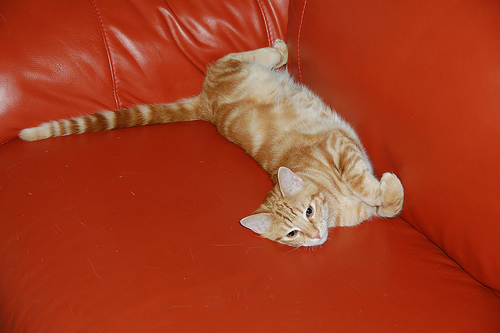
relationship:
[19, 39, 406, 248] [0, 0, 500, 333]
cat lying on a couch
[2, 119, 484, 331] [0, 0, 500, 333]
cushion of a couch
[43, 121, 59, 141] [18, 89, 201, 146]
stripe on tail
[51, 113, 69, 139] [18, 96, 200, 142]
stripe on tail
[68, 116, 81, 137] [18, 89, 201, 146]
stripe on tail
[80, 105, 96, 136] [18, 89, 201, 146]
stripe on tail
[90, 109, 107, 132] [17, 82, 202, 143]
stripe on tail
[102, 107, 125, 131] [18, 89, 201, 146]
stripe on tail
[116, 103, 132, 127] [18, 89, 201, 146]
stripe on tail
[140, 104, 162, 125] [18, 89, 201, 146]
stripe on tail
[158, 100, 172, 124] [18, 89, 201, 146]
stripe on tail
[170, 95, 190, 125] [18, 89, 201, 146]
stripe on tail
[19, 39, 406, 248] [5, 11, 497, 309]
cat laying on a couch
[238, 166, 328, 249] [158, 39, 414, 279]
head of a cat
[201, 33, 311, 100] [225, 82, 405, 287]
feet of a cat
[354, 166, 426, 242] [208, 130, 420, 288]
paws on cat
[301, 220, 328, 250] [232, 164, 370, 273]
nose on cat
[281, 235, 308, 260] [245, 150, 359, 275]
whiskers on cat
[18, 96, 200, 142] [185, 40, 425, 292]
tail of a cat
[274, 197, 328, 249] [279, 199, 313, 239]
cat with eyes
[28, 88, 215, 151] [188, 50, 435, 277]
tail of a cat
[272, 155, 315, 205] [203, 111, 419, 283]
ear of a cat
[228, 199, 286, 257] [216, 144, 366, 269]
ear of a cat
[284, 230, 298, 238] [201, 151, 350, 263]
eye of a cat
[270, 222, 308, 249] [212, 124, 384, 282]
eye of a cat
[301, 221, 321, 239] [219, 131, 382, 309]
nose of a cat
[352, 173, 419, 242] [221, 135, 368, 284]
legs of a cat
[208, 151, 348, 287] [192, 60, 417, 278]
head of a cat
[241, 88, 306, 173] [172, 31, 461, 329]
fur of a cat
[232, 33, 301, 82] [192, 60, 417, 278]
legs of a cat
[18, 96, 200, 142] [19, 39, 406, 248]
tail of cat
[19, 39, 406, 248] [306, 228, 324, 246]
cat with a nose